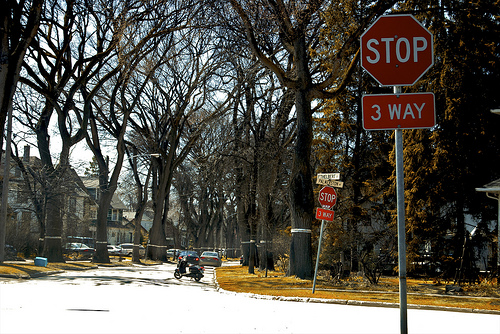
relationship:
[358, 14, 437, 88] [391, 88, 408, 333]
stop sign on post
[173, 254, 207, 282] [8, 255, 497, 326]
motorcycle in road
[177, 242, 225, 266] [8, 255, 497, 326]
cars on road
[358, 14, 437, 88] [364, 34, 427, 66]
stop sign has text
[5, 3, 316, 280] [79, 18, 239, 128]
trees have branches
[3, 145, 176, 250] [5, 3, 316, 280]
houses behind trees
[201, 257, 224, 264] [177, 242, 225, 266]
tail lights on cars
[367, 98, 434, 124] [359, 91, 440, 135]
3 way on sign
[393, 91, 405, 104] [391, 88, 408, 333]
bolt on post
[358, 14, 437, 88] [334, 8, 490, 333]
stop sign on right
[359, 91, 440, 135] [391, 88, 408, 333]
sign on post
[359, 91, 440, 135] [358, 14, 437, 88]
sign under stop sign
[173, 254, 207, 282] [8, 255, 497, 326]
motorcycle on road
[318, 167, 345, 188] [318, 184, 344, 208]
street sign above stop sign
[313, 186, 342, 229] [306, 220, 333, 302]
sign on pole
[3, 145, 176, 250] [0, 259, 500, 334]
houses on road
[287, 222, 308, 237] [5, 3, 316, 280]
band on trees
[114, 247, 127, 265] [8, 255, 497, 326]
mailbox on road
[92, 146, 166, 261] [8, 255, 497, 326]
street light on road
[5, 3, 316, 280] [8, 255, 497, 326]
trees along road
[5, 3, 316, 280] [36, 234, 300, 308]
trees on either side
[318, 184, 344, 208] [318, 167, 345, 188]
stop sign under street sign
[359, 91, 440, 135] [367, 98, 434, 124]
sign says 3 way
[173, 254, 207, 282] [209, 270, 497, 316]
motorcycle at curb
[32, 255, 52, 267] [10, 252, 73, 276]
box on grass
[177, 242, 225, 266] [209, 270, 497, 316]
cars at curb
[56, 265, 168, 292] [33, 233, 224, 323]
shadow on ground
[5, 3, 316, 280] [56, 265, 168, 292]
trees cast shadow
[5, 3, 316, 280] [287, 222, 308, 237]
trees have band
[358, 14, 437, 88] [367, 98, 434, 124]
stop sign on 3 way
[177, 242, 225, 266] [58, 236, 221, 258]
cars in driveway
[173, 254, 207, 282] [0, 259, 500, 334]
motorcycle in road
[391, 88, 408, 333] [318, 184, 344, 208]
post has stop sign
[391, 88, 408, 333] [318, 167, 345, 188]
post has street sign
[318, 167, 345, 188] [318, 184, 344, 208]
street sign by stop sign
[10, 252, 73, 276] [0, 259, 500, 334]
grass near road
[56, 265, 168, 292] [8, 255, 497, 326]
shadow on road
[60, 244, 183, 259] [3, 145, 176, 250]
cars near houses